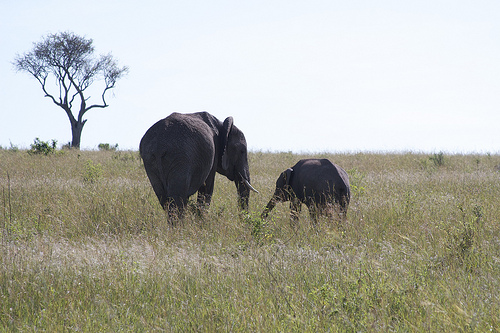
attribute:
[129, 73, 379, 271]
elephant — baby, adult, bab, big, mother, part, body, side, back, standing, grass, walking, gray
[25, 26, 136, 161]
tree — single, lone, lonely, dry, bare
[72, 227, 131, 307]
grass — tall, lighter, a lot, part, brown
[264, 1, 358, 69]
sky — cloud, clear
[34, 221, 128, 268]
plain — part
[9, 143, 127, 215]
park — part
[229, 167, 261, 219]
trunk — part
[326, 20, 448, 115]
sun — shining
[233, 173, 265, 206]
tusk — white